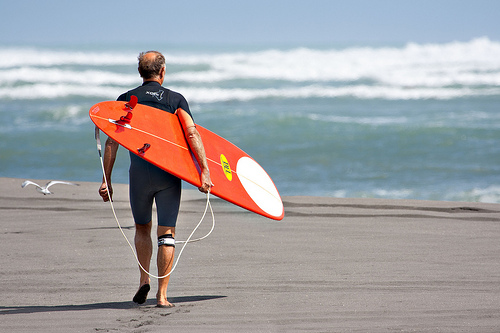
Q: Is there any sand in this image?
A: Yes, there is sand.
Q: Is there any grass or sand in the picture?
A: Yes, there is sand.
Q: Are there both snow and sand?
A: No, there is sand but no snow.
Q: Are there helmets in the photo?
A: No, there are no helmets.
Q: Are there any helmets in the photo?
A: No, there are no helmets.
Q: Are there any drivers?
A: No, there are no drivers.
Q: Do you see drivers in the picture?
A: No, there are no drivers.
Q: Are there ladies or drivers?
A: No, there are no drivers or ladies.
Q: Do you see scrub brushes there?
A: No, there are no scrub brushes.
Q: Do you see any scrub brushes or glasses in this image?
A: No, there are no scrub brushes or glasses.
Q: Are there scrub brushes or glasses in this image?
A: No, there are no scrub brushes or glasses.